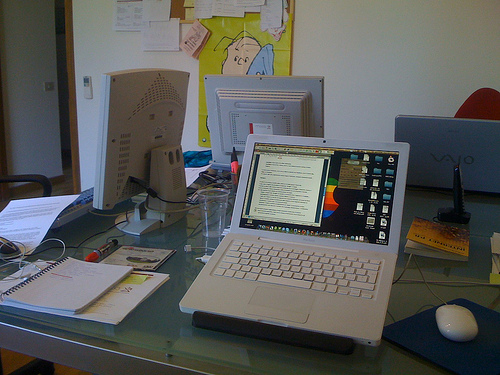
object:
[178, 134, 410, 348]
laptop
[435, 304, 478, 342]
mouse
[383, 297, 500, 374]
mousepad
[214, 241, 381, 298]
keyboard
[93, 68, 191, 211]
monitors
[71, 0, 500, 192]
wall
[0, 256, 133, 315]
notebook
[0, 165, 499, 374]
table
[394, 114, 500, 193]
laptop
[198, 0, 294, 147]
poster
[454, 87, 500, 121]
chair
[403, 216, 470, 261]
cover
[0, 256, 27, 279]
mousepad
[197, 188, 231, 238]
glass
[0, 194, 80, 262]
paper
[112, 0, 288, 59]
bulletin board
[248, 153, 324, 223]
document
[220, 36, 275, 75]
linus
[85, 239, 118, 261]
marker